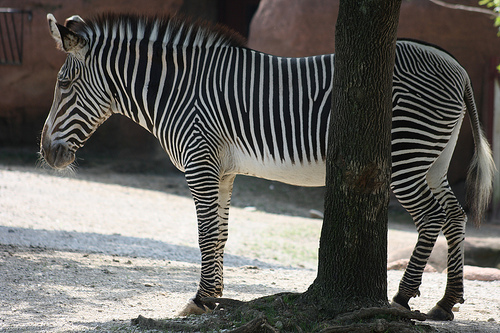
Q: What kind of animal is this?
A: A Zebra.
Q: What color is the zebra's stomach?
A: White.